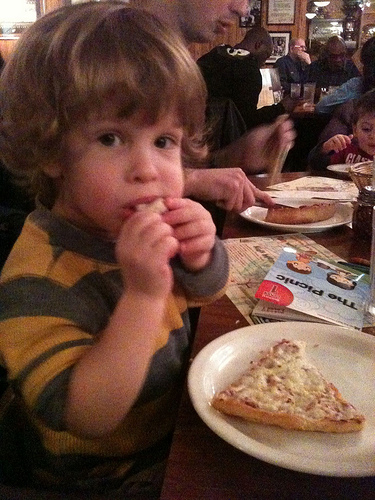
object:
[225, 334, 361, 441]
food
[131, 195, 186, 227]
food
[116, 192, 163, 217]
mouth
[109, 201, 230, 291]
hands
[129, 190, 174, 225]
food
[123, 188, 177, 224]
mouth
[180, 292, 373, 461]
plate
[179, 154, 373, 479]
table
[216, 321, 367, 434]
pizza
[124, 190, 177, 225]
food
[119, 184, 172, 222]
mouth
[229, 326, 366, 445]
pizza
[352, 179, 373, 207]
top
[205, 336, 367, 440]
pizza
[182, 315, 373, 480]
plate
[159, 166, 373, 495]
table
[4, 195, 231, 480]
sweater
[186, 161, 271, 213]
hand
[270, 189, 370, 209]
knife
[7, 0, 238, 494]
child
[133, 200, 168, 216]
food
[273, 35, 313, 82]
man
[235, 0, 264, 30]
picture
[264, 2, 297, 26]
picture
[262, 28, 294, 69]
picture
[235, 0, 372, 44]
wall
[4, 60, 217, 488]
young kid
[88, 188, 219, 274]
hands bringing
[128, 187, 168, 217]
piece of food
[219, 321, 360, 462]
cheese pizza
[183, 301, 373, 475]
white plate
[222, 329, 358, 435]
slice of pizza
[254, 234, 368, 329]
kids book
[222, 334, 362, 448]
plate filled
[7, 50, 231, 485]
little boy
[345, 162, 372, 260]
small glass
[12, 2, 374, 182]
group of people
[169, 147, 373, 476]
wooden table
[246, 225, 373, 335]
book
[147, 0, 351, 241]
man eating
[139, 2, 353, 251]
man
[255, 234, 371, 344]
coloring book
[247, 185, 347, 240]
person cutting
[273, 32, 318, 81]
gentleman cleaning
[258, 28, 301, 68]
decorative picture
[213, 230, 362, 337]
restaurant menu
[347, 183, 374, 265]
metal shaker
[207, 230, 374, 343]
standing menus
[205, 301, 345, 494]
bread basket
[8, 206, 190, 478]
grey shirt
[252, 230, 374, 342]
childs book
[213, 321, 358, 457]
pizza slice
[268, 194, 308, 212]
plastic knife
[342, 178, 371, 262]
glass shaker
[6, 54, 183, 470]
child sitting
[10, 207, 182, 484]
child wearing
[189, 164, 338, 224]
right hand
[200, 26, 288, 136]
man weariing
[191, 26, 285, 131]
man wearing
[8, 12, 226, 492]
child biting